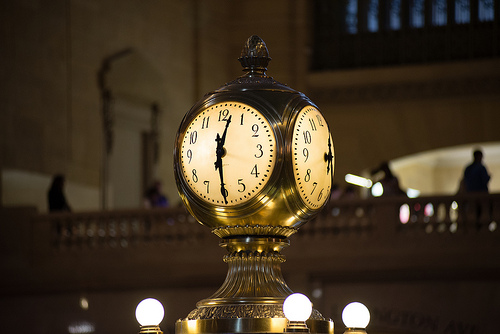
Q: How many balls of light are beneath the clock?
A: Three.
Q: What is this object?
A: Clock.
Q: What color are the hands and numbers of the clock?
A: Black.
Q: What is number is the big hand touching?
A: 6.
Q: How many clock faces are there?
A: Two.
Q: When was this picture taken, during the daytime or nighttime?
A: Nighttime.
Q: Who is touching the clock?
A: No one.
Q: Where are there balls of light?
A: Below the clock.